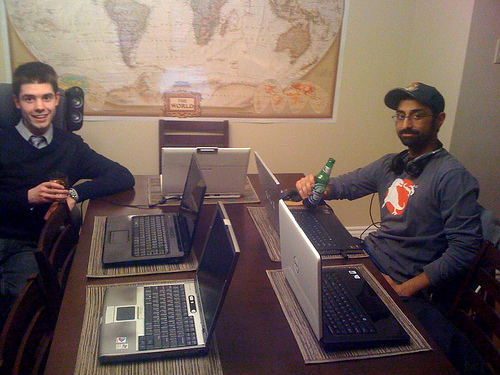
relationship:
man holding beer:
[295, 78, 486, 297] [300, 154, 336, 213]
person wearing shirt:
[294, 81, 486, 298] [326, 150, 484, 287]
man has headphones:
[295, 78, 486, 297] [391, 140, 444, 179]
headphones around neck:
[391, 140, 444, 179] [406, 130, 439, 160]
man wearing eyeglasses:
[295, 78, 486, 297] [389, 110, 440, 124]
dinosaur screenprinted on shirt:
[379, 177, 418, 221] [315, 145, 485, 288]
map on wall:
[2, 0, 351, 124] [0, 0, 420, 242]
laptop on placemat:
[278, 199, 409, 350] [263, 260, 434, 367]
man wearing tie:
[0, 61, 136, 305] [27, 135, 47, 147]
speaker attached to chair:
[70, 94, 84, 106] [0, 80, 70, 135]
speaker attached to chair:
[68, 110, 83, 124] [0, 80, 70, 135]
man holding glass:
[0, 61, 136, 305] [48, 166, 70, 195]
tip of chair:
[157, 117, 230, 133] [157, 119, 230, 176]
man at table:
[295, 78, 486, 297] [42, 171, 455, 372]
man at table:
[0, 61, 136, 305] [42, 171, 455, 372]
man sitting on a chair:
[4, 61, 110, 204] [58, 86, 82, 114]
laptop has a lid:
[159, 140, 246, 199] [205, 160, 230, 175]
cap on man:
[377, 77, 453, 124] [315, 86, 476, 313]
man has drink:
[0, 61, 136, 305] [52, 166, 72, 186]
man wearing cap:
[295, 78, 486, 297] [378, 68, 449, 112]